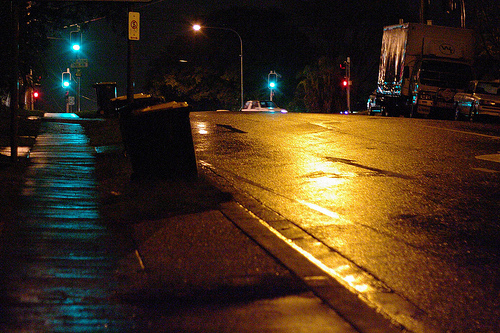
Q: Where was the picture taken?
A: It was taken at the street.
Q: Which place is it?
A: It is a street.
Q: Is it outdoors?
A: Yes, it is outdoors.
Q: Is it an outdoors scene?
A: Yes, it is outdoors.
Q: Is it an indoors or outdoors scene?
A: It is outdoors.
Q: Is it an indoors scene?
A: No, it is outdoors.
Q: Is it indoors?
A: No, it is outdoors.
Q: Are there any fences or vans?
A: No, there are no fences or vans.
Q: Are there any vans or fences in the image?
A: No, there are no fences or vans.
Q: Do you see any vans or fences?
A: No, there are no fences or vans.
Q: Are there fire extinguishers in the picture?
A: No, there are no fire extinguishers.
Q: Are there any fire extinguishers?
A: No, there are no fire extinguishers.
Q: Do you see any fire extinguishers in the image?
A: No, there are no fire extinguishers.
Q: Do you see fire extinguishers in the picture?
A: No, there are no fire extinguishers.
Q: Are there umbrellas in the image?
A: No, there are no umbrellas.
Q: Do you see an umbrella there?
A: No, there are no umbrellas.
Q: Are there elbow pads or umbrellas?
A: No, there are no umbrellas or elbow pads.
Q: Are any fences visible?
A: No, there are no fences.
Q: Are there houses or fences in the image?
A: No, there are no fences or houses.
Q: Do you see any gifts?
A: No, there are no gifts.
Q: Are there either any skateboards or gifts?
A: No, there are no gifts or skateboards.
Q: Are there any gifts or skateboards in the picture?
A: No, there are no gifts or skateboards.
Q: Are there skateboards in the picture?
A: No, there are no skateboards.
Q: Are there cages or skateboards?
A: No, there are no skateboards or cages.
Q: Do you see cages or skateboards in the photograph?
A: No, there are no skateboards or cages.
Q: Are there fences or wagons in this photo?
A: No, there are no fences or wagons.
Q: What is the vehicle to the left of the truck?
A: The vehicle is a car.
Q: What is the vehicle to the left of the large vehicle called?
A: The vehicle is a car.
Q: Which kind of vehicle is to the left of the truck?
A: The vehicle is a car.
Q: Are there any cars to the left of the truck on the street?
A: Yes, there is a car to the left of the truck.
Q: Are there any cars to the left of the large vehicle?
A: Yes, there is a car to the left of the truck.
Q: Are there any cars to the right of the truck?
A: No, the car is to the left of the truck.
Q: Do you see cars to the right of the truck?
A: No, the car is to the left of the truck.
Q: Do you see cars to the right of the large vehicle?
A: No, the car is to the left of the truck.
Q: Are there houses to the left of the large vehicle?
A: No, there is a car to the left of the truck.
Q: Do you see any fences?
A: No, there are no fences.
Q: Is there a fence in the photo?
A: No, there are no fences.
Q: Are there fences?
A: No, there are no fences.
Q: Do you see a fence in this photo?
A: No, there are no fences.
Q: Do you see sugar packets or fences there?
A: No, there are no fences or sugar packets.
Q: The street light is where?
A: The street light is on the street.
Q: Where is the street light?
A: The street light is on the street.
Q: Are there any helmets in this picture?
A: No, there are no helmets.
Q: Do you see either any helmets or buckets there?
A: No, there are no helmets or buckets.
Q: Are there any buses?
A: No, there are no buses.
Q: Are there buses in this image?
A: No, there are no buses.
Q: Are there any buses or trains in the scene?
A: No, there are no buses or trains.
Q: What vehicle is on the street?
A: The vehicle is a car.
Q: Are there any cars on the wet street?
A: Yes, there is a car on the street.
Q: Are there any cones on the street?
A: No, there is a car on the street.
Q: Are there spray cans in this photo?
A: No, there are no spray cans.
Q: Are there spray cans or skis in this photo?
A: No, there are no spray cans or skis.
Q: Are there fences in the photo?
A: No, there are no fences.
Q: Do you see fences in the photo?
A: No, there are no fences.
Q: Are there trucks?
A: Yes, there is a truck.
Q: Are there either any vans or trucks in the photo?
A: Yes, there is a truck.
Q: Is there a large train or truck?
A: Yes, there is a large truck.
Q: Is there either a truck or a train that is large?
A: Yes, the truck is large.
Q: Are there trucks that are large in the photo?
A: Yes, there is a large truck.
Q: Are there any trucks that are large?
A: Yes, there is a truck that is large.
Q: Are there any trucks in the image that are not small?
A: Yes, there is a large truck.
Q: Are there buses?
A: No, there are no buses.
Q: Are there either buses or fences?
A: No, there are no buses or fences.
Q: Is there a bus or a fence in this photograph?
A: No, there are no buses or fences.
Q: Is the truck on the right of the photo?
A: Yes, the truck is on the right of the image.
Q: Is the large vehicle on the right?
A: Yes, the truck is on the right of the image.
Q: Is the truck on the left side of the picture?
A: No, the truck is on the right of the image.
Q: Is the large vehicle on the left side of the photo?
A: No, the truck is on the right of the image.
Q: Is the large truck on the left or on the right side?
A: The truck is on the right of the image.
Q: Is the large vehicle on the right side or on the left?
A: The truck is on the right of the image.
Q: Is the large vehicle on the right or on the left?
A: The truck is on the right of the image.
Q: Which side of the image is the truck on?
A: The truck is on the right of the image.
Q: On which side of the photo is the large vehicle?
A: The truck is on the right of the image.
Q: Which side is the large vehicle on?
A: The truck is on the right of the image.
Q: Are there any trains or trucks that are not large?
A: No, there is a truck but it is large.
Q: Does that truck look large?
A: Yes, the truck is large.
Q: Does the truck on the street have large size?
A: Yes, the truck is large.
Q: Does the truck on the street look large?
A: Yes, the truck is large.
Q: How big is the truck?
A: The truck is large.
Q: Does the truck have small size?
A: No, the truck is large.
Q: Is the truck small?
A: No, the truck is large.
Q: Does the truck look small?
A: No, the truck is large.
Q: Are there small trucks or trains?
A: No, there is a truck but it is large.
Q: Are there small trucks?
A: No, there is a truck but it is large.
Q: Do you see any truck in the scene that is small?
A: No, there is a truck but it is large.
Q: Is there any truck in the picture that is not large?
A: No, there is a truck but it is large.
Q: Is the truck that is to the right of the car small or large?
A: The truck is large.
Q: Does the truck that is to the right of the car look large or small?
A: The truck is large.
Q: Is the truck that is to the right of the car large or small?
A: The truck is large.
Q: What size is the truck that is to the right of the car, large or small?
A: The truck is large.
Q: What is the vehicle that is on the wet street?
A: The vehicle is a truck.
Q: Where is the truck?
A: The truck is on the street.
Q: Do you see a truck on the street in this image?
A: Yes, there is a truck on the street.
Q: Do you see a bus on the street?
A: No, there is a truck on the street.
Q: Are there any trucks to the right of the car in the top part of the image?
A: Yes, there is a truck to the right of the car.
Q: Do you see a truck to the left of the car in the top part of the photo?
A: No, the truck is to the right of the car.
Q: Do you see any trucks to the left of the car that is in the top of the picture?
A: No, the truck is to the right of the car.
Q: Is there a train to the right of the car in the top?
A: No, there is a truck to the right of the car.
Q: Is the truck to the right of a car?
A: Yes, the truck is to the right of a car.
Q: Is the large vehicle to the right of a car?
A: Yes, the truck is to the right of a car.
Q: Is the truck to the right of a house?
A: No, the truck is to the right of a car.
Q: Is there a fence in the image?
A: No, there are no fences.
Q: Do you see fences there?
A: No, there are no fences.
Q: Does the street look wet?
A: Yes, the street is wet.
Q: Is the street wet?
A: Yes, the street is wet.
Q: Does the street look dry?
A: No, the street is wet.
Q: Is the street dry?
A: No, the street is wet.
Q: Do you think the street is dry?
A: No, the street is wet.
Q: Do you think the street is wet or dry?
A: The street is wet.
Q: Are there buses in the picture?
A: No, there are no buses.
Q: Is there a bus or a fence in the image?
A: No, there are no buses or fences.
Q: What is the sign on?
A: The sign is on the post.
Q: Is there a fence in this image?
A: No, there are no fences.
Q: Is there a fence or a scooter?
A: No, there are no fences or scooters.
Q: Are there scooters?
A: No, there are no scooters.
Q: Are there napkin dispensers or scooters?
A: No, there are no scooters or napkin dispensers.